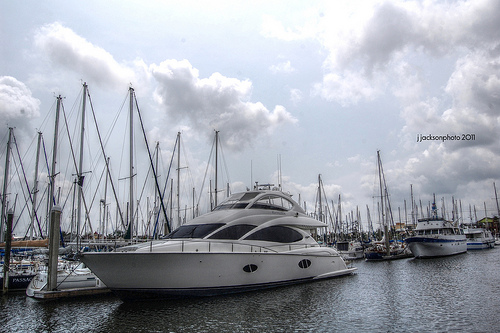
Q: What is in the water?
A: A yacht.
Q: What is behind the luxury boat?
A: A group of masts.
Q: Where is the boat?
A: In the water.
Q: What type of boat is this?
A: A yacht.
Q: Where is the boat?
A: In a seaport.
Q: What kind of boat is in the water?
A: A luxurious yacht.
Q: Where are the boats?
A: In the water.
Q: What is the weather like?
A: Cloudy.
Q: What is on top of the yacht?
A: A radar.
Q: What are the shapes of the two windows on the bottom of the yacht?
A: Oval shape.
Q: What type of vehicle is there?
A: Boats.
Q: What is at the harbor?
A: Boats.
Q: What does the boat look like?
A: White.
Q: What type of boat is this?
A: Yacht.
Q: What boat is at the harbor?
A: A yacht.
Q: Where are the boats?
A: In the water.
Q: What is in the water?
A: A ship.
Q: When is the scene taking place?
A: Daytime.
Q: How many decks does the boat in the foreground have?
A: One.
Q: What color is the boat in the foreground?
A: White.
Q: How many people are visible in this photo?
A: None.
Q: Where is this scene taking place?
A: Ocean.